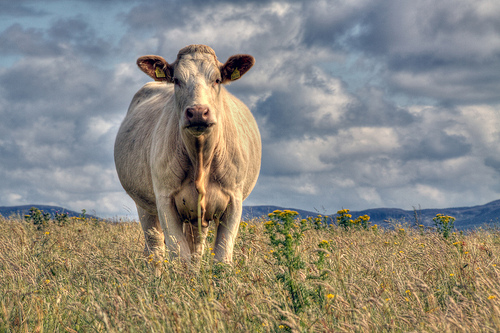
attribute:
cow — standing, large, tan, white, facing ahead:
[112, 44, 263, 267]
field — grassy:
[3, 205, 500, 331]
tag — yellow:
[154, 66, 165, 78]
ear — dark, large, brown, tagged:
[136, 54, 173, 84]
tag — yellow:
[230, 68, 240, 80]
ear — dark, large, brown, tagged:
[222, 55, 257, 82]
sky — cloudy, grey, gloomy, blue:
[1, 1, 498, 221]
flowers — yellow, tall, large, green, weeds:
[20, 205, 499, 332]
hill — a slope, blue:
[0, 199, 499, 226]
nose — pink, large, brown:
[185, 106, 209, 124]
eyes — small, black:
[172, 77, 221, 87]